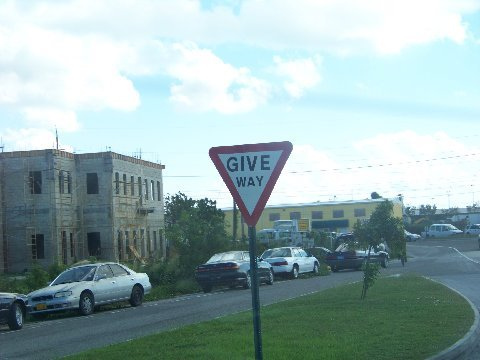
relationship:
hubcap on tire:
[83, 297, 93, 312] [77, 290, 96, 317]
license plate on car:
[35, 304, 47, 310] [24, 262, 153, 316]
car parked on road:
[194, 251, 276, 292] [0, 237, 478, 358]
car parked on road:
[260, 245, 322, 278] [0, 237, 478, 358]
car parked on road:
[327, 238, 389, 272] [0, 237, 478, 358]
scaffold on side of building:
[0, 150, 154, 273] [1, 148, 168, 276]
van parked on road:
[428, 221, 460, 236] [405, 235, 479, 308]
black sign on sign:
[208, 139, 292, 226] [207, 141, 293, 225]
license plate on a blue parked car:
[29, 301, 56, 317] [27, 260, 151, 317]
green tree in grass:
[344, 198, 408, 301] [348, 319, 423, 348]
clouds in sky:
[367, 64, 443, 118] [45, 29, 165, 97]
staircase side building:
[130, 243, 150, 266] [0, 130, 96, 302]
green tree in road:
[344, 198, 408, 301] [425, 230, 456, 303]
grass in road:
[373, 287, 402, 327] [434, 217, 470, 288]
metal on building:
[125, 189, 159, 257] [15, 135, 184, 290]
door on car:
[221, 252, 318, 276] [198, 231, 276, 293]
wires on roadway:
[380, 154, 441, 169] [432, 230, 477, 266]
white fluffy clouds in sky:
[58, 24, 266, 115] [348, 34, 437, 124]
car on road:
[327, 238, 389, 272] [451, 254, 473, 285]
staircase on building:
[120, 221, 163, 276] [1, 127, 187, 299]